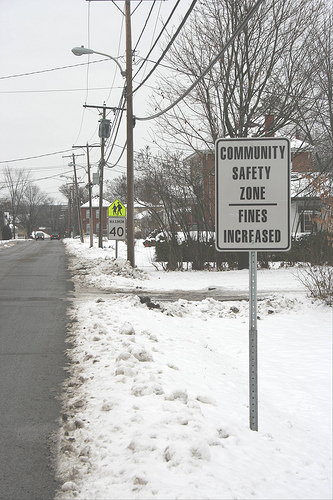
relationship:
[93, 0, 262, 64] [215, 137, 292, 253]
power lines above sign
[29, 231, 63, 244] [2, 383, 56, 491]
cars on road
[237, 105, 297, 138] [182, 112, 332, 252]
chimney on house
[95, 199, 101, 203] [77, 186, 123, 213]
snow on roof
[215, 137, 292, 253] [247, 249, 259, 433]
sign on pole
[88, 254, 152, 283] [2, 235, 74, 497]
snow pile along side road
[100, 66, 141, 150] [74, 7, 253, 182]
pole with wires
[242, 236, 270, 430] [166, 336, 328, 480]
post sticking out of snow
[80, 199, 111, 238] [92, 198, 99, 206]
house with snow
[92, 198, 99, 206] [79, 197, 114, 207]
snow on roof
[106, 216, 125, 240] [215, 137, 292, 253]
sign on sign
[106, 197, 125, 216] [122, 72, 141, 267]
sign on pole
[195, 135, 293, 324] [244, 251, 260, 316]
sign on pole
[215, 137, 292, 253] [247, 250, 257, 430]
sign on pole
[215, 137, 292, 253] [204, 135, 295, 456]
sign on pole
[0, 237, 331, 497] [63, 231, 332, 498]
ground covered in snow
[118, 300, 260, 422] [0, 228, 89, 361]
snow on side of road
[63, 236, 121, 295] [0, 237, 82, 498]
snow on side of road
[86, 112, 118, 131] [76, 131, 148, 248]
transformer on pole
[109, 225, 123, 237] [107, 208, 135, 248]
40 on sign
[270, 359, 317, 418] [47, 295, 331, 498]
patch on snow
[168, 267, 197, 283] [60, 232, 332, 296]
patch on snow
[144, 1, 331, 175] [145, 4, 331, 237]
branches on tree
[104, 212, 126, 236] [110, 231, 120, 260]
street sign on pole